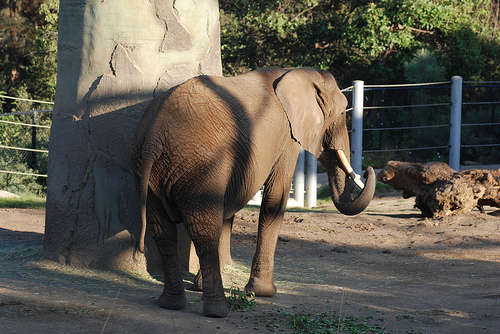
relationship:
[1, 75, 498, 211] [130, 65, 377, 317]
fence to contain elephant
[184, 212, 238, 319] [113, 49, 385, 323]
leg of an elephant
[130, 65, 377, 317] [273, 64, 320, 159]
elephant has ear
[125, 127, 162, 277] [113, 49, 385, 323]
tail of elephant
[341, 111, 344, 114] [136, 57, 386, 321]
eye of elephant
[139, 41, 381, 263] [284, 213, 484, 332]
elephant standing on dirt ground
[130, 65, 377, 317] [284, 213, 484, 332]
elephant standing on dirt ground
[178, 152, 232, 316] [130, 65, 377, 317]
leg attached to elephant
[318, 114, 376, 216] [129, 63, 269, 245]
trunk attached to elephant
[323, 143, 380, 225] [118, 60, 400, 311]
trunk attached to elephant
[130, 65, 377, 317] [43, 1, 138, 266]
elephant leaning on tree trunk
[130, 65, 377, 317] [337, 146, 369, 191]
elephant has tusks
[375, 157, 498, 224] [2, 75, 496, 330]
tree trunk in cage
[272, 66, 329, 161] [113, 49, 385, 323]
ear of elephant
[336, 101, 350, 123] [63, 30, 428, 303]
eye of elephant